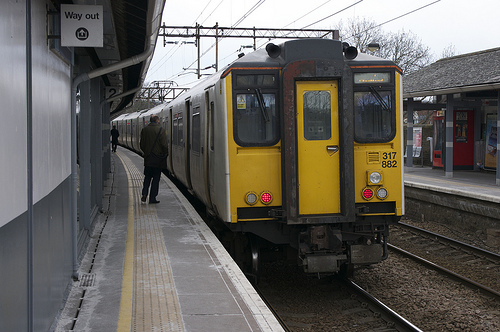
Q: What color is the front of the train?
A: Yellow.